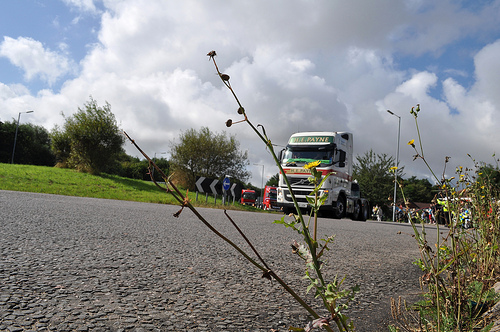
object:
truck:
[274, 125, 382, 223]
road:
[0, 187, 475, 330]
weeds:
[455, 272, 500, 309]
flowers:
[300, 152, 327, 184]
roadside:
[263, 289, 408, 327]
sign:
[217, 175, 235, 192]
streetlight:
[7, 106, 36, 167]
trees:
[46, 94, 129, 168]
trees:
[167, 123, 251, 192]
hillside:
[0, 161, 241, 209]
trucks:
[236, 187, 260, 207]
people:
[423, 205, 437, 224]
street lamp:
[385, 107, 406, 222]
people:
[395, 203, 405, 223]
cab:
[279, 144, 334, 169]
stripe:
[277, 158, 333, 164]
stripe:
[275, 168, 335, 175]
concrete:
[1, 191, 443, 327]